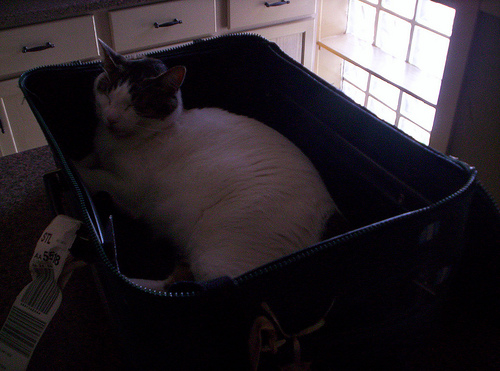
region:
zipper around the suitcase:
[427, 152, 492, 230]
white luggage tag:
[0, 197, 105, 367]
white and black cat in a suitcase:
[40, 27, 379, 319]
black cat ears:
[62, 25, 215, 132]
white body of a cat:
[120, 92, 350, 306]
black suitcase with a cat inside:
[7, 34, 498, 364]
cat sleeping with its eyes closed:
[95, 84, 170, 117]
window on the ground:
[334, 0, 466, 120]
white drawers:
[1, 20, 106, 78]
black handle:
[13, 40, 64, 62]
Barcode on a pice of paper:
[24, 278, 54, 312]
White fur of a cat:
[181, 138, 271, 194]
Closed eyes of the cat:
[101, 92, 140, 108]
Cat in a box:
[21, 68, 472, 254]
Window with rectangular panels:
[345, 66, 442, 101]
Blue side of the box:
[364, 237, 403, 272]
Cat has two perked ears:
[93, 47, 193, 85]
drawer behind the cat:
[1, 18, 86, 68]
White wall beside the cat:
[470, 62, 491, 122]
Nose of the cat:
[101, 108, 120, 123]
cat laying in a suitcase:
[18, 30, 476, 325]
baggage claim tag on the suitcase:
[7, 197, 79, 367]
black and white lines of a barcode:
[3, 305, 43, 361]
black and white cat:
[62, 44, 317, 286]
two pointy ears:
[90, 33, 192, 96]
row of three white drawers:
[1, 1, 308, 64]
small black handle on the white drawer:
[12, 33, 62, 58]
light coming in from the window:
[339, 0, 438, 150]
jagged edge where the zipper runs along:
[112, 255, 194, 301]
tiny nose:
[104, 111, 119, 126]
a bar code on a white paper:
[19, 262, 60, 313]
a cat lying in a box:
[73, 36, 349, 291]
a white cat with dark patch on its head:
[78, 37, 349, 287]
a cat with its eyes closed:
[69, 36, 349, 289]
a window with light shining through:
[318, 0, 455, 148]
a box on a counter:
[18, 33, 480, 302]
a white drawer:
[104, 2, 219, 50]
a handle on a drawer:
[19, 41, 56, 54]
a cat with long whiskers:
[79, 37, 351, 289]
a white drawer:
[1, 15, 103, 75]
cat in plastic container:
[83, 35, 310, 246]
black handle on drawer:
[156, 12, 191, 37]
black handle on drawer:
[261, 0, 297, 13]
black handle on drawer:
[13, 34, 56, 61]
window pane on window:
[405, 27, 440, 74]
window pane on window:
[371, 15, 402, 61]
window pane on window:
[347, 8, 369, 45]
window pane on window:
[398, 102, 429, 127]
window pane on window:
[368, 85, 393, 105]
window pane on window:
[338, 62, 363, 83]